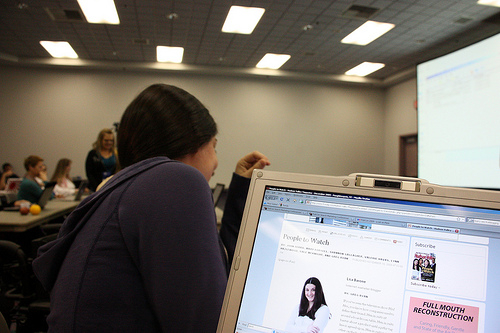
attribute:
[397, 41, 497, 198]
screen — giant, white, glowing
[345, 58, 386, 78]
lights — rectangular, white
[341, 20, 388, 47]
lights — white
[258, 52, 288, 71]
lights — white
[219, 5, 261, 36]
lights — white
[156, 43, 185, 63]
lights — white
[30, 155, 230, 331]
hoodie — purple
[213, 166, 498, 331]
laptop — silver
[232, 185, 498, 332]
screen — computer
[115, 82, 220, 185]
hair — shiny, brown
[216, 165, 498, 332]
computer — screen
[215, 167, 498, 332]
computer screen — on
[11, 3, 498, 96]
tiles — square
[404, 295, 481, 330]
advertisement — pink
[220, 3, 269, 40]
light — rectangle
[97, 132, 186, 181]
hair — dark, long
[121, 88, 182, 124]
hair — dark, colored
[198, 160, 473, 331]
screen — computer 